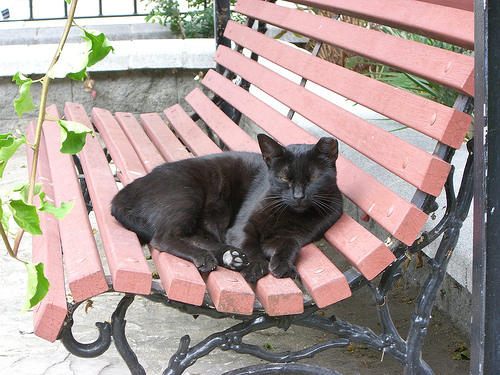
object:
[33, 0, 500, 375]
wooden beams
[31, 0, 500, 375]
bench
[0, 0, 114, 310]
branch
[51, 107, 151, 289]
wood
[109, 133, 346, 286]
cat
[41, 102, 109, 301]
slat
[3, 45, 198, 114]
blocks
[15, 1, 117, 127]
stem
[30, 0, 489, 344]
seat